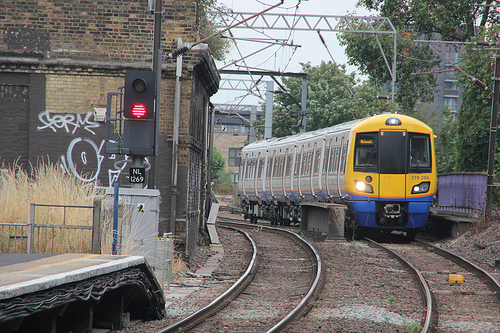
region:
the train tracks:
[422, 294, 497, 331]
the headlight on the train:
[353, 179, 369, 193]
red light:
[130, 99, 150, 116]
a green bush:
[311, 74, 355, 117]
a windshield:
[355, 139, 377, 169]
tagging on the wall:
[25, 100, 101, 175]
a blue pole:
[106, 179, 130, 246]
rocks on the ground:
[332, 270, 368, 327]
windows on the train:
[306, 154, 353, 174]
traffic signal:
[124, 74, 154, 122]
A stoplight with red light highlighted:
[119, 66, 157, 158]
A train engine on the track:
[237, 112, 437, 239]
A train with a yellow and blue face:
[235, 113, 436, 241]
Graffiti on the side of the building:
[36, 41, 150, 190]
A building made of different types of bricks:
[1, 33, 226, 253]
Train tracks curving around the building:
[151, 187, 498, 331]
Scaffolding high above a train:
[193, 6, 408, 147]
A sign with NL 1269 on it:
[126, 164, 149, 186]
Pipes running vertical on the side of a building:
[153, 32, 218, 261]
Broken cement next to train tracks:
[152, 189, 290, 332]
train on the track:
[224, 111, 453, 248]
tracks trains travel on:
[221, 245, 488, 297]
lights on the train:
[342, 164, 441, 194]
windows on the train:
[356, 135, 430, 166]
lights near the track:
[112, 68, 162, 122]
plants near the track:
[6, 160, 121, 235]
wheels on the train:
[242, 203, 302, 223]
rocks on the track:
[343, 259, 387, 291]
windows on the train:
[242, 155, 347, 172]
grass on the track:
[391, 308, 421, 331]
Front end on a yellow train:
[344, 108, 436, 232]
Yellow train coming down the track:
[236, 111, 438, 240]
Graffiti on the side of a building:
[31, 103, 124, 200]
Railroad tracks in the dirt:
[153, 244, 497, 331]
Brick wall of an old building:
[54, 7, 151, 62]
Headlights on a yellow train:
[353, 180, 432, 193]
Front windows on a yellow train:
[354, 126, 433, 173]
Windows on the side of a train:
[238, 138, 353, 180]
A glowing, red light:
[130, 102, 148, 118]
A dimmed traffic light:
[129, 77, 149, 94]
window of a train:
[357, 135, 376, 172]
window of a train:
[412, 134, 428, 179]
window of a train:
[334, 152, 340, 180]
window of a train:
[323, 151, 340, 179]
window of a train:
[308, 148, 332, 186]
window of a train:
[305, 142, 327, 176]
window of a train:
[280, 155, 302, 177]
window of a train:
[268, 145, 293, 182]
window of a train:
[258, 150, 276, 179]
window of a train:
[240, 154, 266, 182]